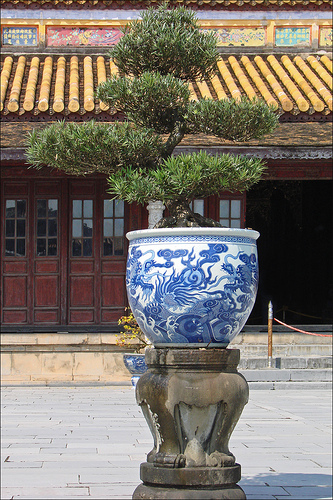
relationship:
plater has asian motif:
[117, 220, 263, 351] [126, 239, 249, 341]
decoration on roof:
[5, 3, 327, 53] [3, 3, 332, 172]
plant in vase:
[20, 2, 291, 227] [117, 220, 263, 351]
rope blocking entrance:
[276, 315, 333, 344] [248, 179, 332, 328]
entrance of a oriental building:
[248, 179, 332, 328] [2, 5, 331, 334]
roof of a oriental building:
[3, 3, 332, 172] [2, 5, 331, 334]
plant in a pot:
[20, 2, 291, 227] [117, 220, 263, 351]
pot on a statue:
[117, 220, 263, 351] [132, 346, 252, 499]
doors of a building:
[1, 162, 131, 337] [2, 5, 331, 334]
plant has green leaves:
[20, 2, 291, 227] [103, 7, 222, 76]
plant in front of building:
[20, 2, 291, 227] [2, 5, 331, 334]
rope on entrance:
[276, 315, 333, 344] [248, 179, 332, 328]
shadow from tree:
[238, 467, 332, 499] [20, 2, 291, 227]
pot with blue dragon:
[117, 220, 263, 351] [126, 239, 249, 341]